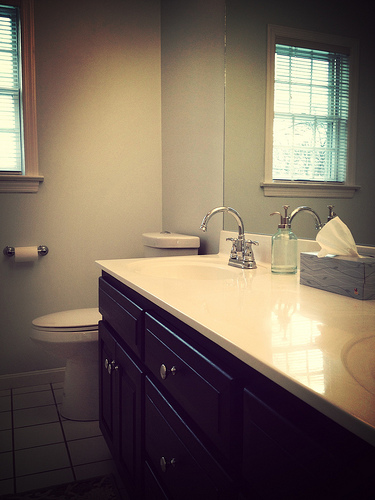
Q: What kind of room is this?
A: Bathroom.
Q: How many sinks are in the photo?
A: One.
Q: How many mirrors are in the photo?
A: One.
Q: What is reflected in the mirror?
A: Window.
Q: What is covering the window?
A: Blinds.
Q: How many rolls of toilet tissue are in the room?
A: One.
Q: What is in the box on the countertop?
A: Tissues.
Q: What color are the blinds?
A: White.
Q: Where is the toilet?
A: In the bathroom.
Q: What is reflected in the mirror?
A: A window.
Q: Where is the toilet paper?
A: On the wall.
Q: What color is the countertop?
A: White.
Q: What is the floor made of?
A: Tile.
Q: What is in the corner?
A: Toilet.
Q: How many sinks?
A: Two.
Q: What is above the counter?
A: Mirror.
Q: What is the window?
A: Above the toilet paper.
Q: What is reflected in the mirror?
A: Window.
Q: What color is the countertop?
A: White.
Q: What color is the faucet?
A: Silver chrome.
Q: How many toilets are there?
A: One.